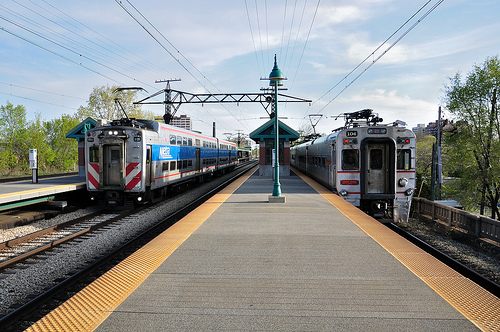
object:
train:
[84, 117, 239, 210]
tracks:
[0, 191, 126, 270]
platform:
[202, 216, 330, 293]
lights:
[342, 137, 411, 144]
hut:
[249, 116, 300, 176]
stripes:
[152, 144, 240, 162]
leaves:
[28, 120, 64, 141]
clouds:
[321, 6, 361, 24]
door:
[104, 146, 121, 186]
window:
[90, 147, 99, 162]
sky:
[175, 5, 236, 48]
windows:
[169, 134, 237, 150]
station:
[23, 90, 500, 332]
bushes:
[415, 56, 498, 200]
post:
[268, 54, 285, 196]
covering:
[249, 117, 300, 144]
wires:
[89, 8, 189, 71]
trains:
[84, 117, 417, 209]